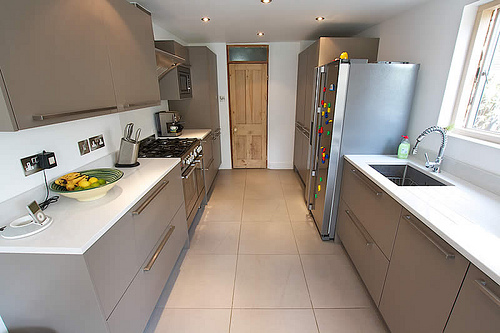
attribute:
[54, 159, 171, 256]
counter — white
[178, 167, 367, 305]
tiles — large, tan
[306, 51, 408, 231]
refrigerator — steel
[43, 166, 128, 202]
bowl — green, large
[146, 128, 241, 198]
oven — steel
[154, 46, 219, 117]
microwave — hanging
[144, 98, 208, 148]
maker — on counter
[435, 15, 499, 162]
window — large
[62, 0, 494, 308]
kitchen — colored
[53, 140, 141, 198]
dish — fruity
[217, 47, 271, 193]
door — wooden, wood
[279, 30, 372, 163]
steel — stainless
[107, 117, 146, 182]
set — colored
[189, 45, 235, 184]
pantry — large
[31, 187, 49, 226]
ipod — charging, docked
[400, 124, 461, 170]
faucet — high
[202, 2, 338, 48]
light — recessed, natural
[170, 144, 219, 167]
range — steel